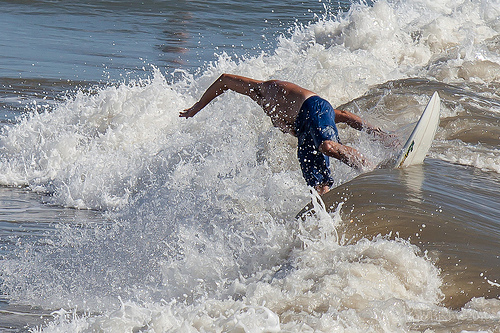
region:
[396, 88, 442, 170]
Rear end of white surfboard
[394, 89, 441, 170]
End of surfboard sticking out of water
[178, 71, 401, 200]
Man riding surfboard on wave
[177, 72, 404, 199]
Man in blue swim trunks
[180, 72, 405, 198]
Shirtless man falling off of surfboard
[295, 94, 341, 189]
Knee length blue swim trunks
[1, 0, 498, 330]
Large body of water with brownish color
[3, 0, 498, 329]
Breaking wave in ocean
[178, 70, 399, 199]
Man with dark tan in water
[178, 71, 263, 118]
Left arm of surfing man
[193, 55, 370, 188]
person in the water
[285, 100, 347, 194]
shorts on the person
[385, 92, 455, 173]
board in the air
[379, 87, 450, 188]
white board under man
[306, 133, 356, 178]
knee of the man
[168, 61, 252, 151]
arm of the man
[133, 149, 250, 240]
white water under the man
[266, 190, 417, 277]
wave forming in the water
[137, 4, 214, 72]
reflection in the water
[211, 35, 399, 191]
man falling over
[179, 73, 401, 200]
surfer in the ocean wearing blue shorts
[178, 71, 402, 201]
surfer on a board about to wipe out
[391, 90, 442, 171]
white surfboard in the ocean being rode by a surfer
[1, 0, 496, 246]
a wave being rode by a surfer who is about to fall off his board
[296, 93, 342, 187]
dark blue shorts of longer length worn by a surfer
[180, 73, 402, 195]
a shirtless man trying to surf on a white surfboard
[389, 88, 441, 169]
white surfboard in the ocean almost completely vertical since the surfer is about to wipe out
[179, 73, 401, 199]
male surfer in an odd position on his surfboard since he is about to fall off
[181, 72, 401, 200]
male surfer with blue shorts captured immediately before falling off his board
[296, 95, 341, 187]
long blue wet shorts worn by a male surfer falling off his board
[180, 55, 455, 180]
person on a surf board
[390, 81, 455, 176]
surf board of the surfer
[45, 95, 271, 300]
rush of water near surfer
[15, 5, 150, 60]
body of water surfer is in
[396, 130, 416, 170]
lettering on the surf board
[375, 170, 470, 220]
water with brown shade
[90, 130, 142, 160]
water white in shade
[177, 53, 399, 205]
surfer in the water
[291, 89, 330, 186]
person wearing blue shorts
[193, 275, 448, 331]
white caps from the waves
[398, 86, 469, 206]
surfboard sticking out of water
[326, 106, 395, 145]
right hand in the water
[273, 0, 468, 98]
waves splashing into surfer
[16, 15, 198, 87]
water is calmer and blue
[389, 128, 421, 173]
logo of surfboard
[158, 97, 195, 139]
water splashing on left hand